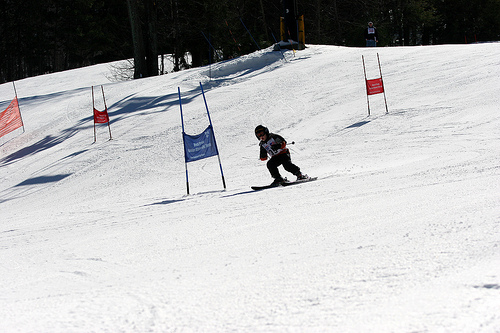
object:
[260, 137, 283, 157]
bib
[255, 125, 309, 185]
contestant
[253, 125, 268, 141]
hat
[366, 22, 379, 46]
skier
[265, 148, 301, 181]
dark pant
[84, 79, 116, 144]
sign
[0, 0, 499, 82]
trees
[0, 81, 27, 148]
fence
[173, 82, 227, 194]
sign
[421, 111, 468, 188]
marks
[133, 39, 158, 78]
base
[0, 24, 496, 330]
hill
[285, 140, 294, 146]
sticks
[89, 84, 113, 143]
gate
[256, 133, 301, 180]
clothes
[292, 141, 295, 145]
tip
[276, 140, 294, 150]
pole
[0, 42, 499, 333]
snow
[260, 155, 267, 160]
hand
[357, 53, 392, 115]
sign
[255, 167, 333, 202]
skis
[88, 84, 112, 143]
marker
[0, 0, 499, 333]
course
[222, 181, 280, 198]
shadow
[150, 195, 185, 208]
shadow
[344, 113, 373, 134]
shadow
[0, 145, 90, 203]
shadow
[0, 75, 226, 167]
shadow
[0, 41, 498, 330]
hillside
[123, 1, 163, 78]
trunk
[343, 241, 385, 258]
marks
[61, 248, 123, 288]
marks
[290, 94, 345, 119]
marks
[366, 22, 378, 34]
bib